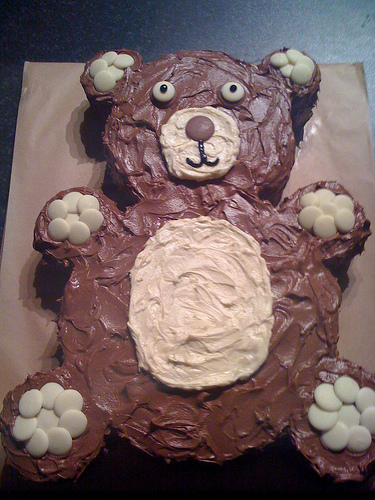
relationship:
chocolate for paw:
[293, 176, 355, 251] [27, 190, 115, 252]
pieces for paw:
[53, 198, 98, 241] [27, 190, 115, 252]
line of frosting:
[195, 144, 203, 161] [182, 141, 204, 170]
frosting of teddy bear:
[182, 141, 204, 170] [10, 28, 374, 488]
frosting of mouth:
[182, 141, 204, 170] [174, 140, 223, 166]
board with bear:
[1, 61, 373, 412] [0, 47, 373, 483]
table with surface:
[1, 0, 374, 499] [241, 12, 306, 41]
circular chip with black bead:
[150, 80, 177, 103] [157, 83, 168, 97]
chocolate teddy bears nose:
[189, 120, 199, 129] [175, 108, 220, 153]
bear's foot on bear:
[288, 352, 373, 484] [0, 47, 375, 483]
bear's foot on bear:
[0, 365, 107, 484] [0, 47, 375, 483]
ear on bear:
[86, 41, 124, 90] [34, 61, 332, 462]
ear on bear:
[264, 47, 323, 88] [34, 61, 332, 462]